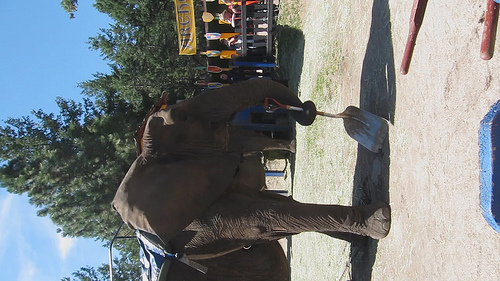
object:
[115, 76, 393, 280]
elephant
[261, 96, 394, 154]
shovel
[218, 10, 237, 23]
person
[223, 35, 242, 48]
person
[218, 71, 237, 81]
person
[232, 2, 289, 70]
fence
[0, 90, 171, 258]
tree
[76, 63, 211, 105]
tree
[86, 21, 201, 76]
tree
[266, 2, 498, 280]
sand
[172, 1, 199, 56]
banner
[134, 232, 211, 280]
blanket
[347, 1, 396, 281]
shadow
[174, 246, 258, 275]
harness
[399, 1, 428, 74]
handle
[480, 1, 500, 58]
handle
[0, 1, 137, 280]
sky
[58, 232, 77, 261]
cloud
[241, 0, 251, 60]
rail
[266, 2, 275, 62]
rail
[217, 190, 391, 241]
leg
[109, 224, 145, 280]
coach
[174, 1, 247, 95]
shop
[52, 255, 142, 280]
tree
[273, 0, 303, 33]
grass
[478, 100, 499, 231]
object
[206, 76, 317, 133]
trunk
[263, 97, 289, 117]
handle